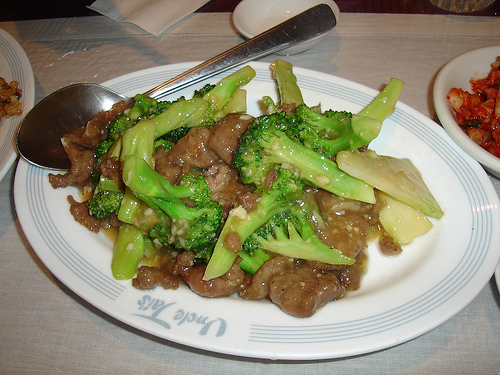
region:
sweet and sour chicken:
[447, 55, 499, 159]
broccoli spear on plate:
[241, 113, 377, 209]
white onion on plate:
[337, 151, 444, 218]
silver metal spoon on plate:
[15, 3, 335, 173]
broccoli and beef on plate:
[59, 62, 438, 316]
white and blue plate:
[14, 59, 499, 359]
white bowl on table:
[434, 47, 499, 175]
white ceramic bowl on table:
[231, 1, 340, 51]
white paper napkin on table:
[87, 2, 212, 34]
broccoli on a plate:
[266, 185, 370, 276]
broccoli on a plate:
[213, 156, 303, 267]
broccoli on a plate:
[125, 139, 223, 256]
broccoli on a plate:
[103, 225, 151, 289]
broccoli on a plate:
[80, 152, 130, 226]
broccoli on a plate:
[136, 79, 253, 151]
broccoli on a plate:
[212, 111, 364, 195]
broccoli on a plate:
[287, 91, 364, 163]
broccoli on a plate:
[255, 63, 313, 120]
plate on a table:
[0, 23, 491, 370]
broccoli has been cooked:
[248, 125, 364, 226]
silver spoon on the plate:
[19, 38, 304, 130]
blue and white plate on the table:
[390, 265, 487, 359]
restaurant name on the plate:
[134, 293, 231, 352]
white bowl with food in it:
[436, 38, 498, 153]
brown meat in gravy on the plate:
[259, 262, 329, 319]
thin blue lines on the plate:
[249, 313, 374, 315]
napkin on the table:
[91, 5, 187, 46]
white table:
[7, 275, 59, 372]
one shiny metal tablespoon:
[17, 6, 340, 178]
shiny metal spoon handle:
[130, 6, 340, 97]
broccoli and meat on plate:
[85, 81, 426, 317]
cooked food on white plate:
[15, 54, 495, 359]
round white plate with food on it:
[13, 32, 493, 367]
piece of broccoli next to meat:
[255, 219, 350, 320]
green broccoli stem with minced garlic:
[234, 104, 384, 203]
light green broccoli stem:
[351, 68, 406, 118]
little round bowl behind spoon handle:
[228, 2, 342, 56]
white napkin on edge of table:
[85, 4, 200, 56]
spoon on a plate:
[171, 1, 343, 57]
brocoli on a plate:
[261, 220, 342, 265]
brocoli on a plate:
[266, 167, 294, 202]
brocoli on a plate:
[120, 168, 210, 233]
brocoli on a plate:
[120, 91, 197, 121]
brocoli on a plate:
[298, 105, 350, 137]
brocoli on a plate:
[270, 52, 301, 103]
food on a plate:
[435, 63, 497, 138]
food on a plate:
[115, 70, 430, 300]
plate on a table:
[7, 20, 42, 92]